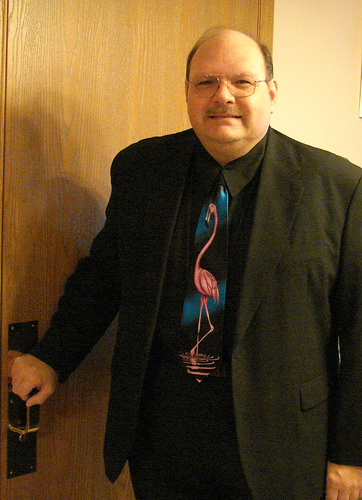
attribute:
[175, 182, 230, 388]
tie — hand-painted, flamingo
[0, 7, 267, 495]
door — wooden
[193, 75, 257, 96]
frames — metal, tintless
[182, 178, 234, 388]
tie — blue, black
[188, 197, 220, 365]
flamingo — pink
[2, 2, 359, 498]
wooden door — heavy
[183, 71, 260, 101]
eyeglasses — prescription, thin, gold, metal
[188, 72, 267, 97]
glasses — reading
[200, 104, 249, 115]
moustache — brushlike, dark blonde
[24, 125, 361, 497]
suit — black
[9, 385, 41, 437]
handle — brass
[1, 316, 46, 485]
door handle — metallic, goldtone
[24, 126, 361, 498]
blazer — black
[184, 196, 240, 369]
pink flamingo — bird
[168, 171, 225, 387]
necktie — pink, blue, black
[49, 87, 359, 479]
suit — black, two piece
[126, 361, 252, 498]
trousers — black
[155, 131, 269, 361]
shirt — black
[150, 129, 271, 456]
shirt — business, button down, black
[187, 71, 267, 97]
eyeglasses — gold , metal , prescription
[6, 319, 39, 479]
handle — golden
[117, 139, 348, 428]
man's suit — all black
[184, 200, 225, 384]
print — pink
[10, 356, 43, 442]
handle — metal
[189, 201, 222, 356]
flamingo — pink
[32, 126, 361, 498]
jacket — single-breasted